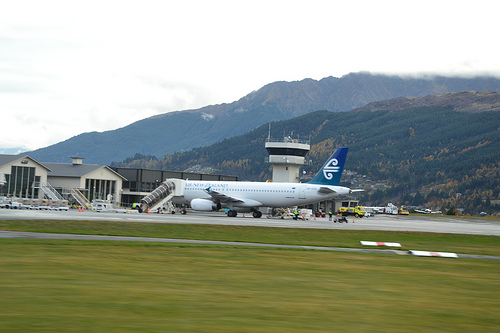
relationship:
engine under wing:
[190, 197, 222, 210] [197, 183, 249, 213]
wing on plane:
[205, 187, 240, 210] [168, 145, 363, 217]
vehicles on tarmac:
[2, 190, 109, 213] [0, 213, 497, 232]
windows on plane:
[189, 183, 296, 192] [106, 102, 358, 222]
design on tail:
[323, 157, 340, 178] [318, 147, 345, 178]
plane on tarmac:
[141, 146, 364, 218] [2, 210, 499, 234]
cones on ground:
[43, 177, 405, 217] [58, 203, 445, 330]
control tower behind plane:
[264, 122, 311, 182] [162, 142, 369, 219]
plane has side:
[141, 146, 364, 218] [177, 180, 320, 205]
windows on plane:
[189, 186, 297, 191] [141, 146, 364, 218]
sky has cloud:
[0, 0, 497, 154] [2, 31, 87, 61]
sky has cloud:
[0, 0, 497, 154] [132, 67, 217, 109]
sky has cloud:
[0, 0, 497, 154] [107, 92, 184, 120]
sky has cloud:
[0, 0, 497, 154] [8, 105, 86, 137]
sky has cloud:
[0, 0, 497, 154] [77, 102, 127, 132]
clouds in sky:
[2, 40, 139, 106] [1, 13, 499, 60]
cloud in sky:
[22, 97, 37, 110] [0, 0, 497, 154]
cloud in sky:
[74, 79, 110, 117] [0, 0, 497, 154]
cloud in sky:
[145, 53, 192, 92] [0, 0, 497, 154]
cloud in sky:
[240, 28, 291, 48] [0, 0, 497, 154]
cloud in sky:
[313, 18, 381, 55] [0, 0, 497, 154]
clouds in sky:
[2, 46, 205, 111] [1, 0, 495, 100]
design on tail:
[323, 157, 340, 178] [308, 145, 348, 182]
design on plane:
[323, 157, 340, 178] [168, 145, 363, 217]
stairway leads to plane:
[134, 179, 177, 216] [164, 164, 359, 221]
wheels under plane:
[226, 208, 263, 218] [141, 146, 364, 218]